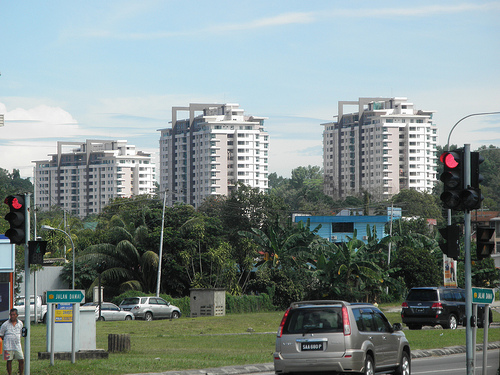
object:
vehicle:
[265, 290, 417, 375]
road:
[409, 335, 498, 374]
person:
[0, 306, 37, 375]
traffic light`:
[4, 190, 30, 213]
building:
[154, 97, 275, 209]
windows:
[276, 304, 348, 337]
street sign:
[39, 286, 88, 307]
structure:
[287, 202, 406, 252]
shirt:
[0, 318, 25, 351]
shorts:
[3, 351, 31, 365]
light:
[4, 190, 29, 212]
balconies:
[207, 137, 223, 145]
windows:
[236, 139, 250, 146]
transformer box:
[185, 283, 231, 318]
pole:
[20, 188, 34, 375]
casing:
[436, 146, 488, 213]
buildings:
[315, 90, 448, 206]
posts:
[64, 304, 81, 367]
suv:
[395, 279, 496, 333]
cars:
[116, 292, 186, 323]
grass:
[0, 288, 500, 375]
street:
[4, 360, 282, 374]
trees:
[176, 214, 209, 280]